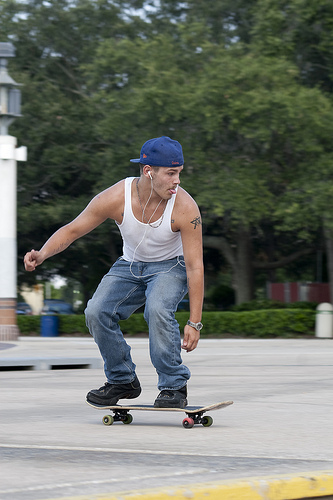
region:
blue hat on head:
[123, 135, 184, 170]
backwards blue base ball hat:
[123, 135, 188, 174]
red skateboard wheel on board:
[184, 417, 194, 426]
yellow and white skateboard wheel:
[101, 413, 119, 424]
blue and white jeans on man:
[77, 258, 193, 395]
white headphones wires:
[126, 183, 191, 280]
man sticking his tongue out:
[140, 149, 185, 202]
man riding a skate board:
[23, 136, 226, 448]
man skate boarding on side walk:
[22, 134, 228, 446]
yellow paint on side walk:
[250, 477, 317, 498]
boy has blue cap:
[124, 130, 194, 186]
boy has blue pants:
[64, 249, 192, 395]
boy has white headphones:
[123, 175, 188, 283]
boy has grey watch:
[184, 302, 213, 349]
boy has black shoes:
[76, 355, 208, 403]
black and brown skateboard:
[86, 379, 226, 421]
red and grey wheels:
[160, 411, 216, 434]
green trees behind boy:
[25, 13, 294, 245]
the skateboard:
[89, 396, 229, 427]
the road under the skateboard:
[10, 423, 328, 486]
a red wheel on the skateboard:
[183, 417, 193, 425]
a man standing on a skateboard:
[87, 132, 234, 407]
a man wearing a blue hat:
[88, 131, 209, 410]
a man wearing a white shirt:
[75, 143, 221, 393]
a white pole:
[314, 299, 332, 337]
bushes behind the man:
[16, 313, 313, 334]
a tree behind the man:
[25, 43, 331, 285]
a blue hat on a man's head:
[130, 135, 185, 166]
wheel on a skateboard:
[181, 417, 192, 428]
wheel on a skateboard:
[101, 414, 113, 425]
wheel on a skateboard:
[121, 412, 132, 423]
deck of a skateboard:
[84, 398, 235, 411]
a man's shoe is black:
[153, 385, 186, 406]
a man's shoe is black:
[88, 377, 140, 402]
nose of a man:
[172, 175, 179, 184]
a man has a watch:
[186, 320, 203, 331]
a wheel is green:
[202, 414, 212, 426]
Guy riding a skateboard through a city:
[24, 135, 233, 426]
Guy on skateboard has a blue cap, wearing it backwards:
[129, 135, 185, 167]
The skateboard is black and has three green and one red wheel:
[85, 399, 232, 426]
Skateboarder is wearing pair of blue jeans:
[82, 254, 189, 388]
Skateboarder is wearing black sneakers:
[83, 378, 185, 406]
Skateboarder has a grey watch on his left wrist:
[184, 319, 200, 327]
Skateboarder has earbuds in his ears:
[127, 169, 183, 274]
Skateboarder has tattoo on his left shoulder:
[188, 214, 200, 226]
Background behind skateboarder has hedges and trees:
[0, 0, 332, 337]